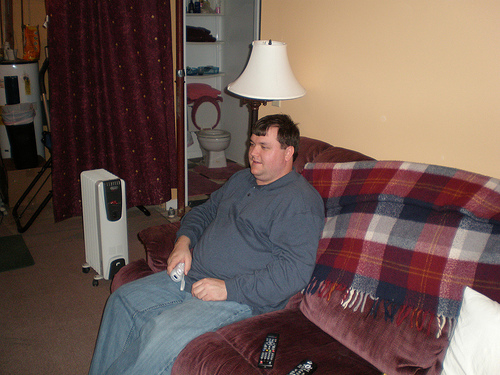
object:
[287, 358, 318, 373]
control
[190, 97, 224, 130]
cover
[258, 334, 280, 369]
controller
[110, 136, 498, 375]
couch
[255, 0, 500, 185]
wall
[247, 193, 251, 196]
button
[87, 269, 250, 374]
jeans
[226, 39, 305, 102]
lampshade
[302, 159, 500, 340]
blanket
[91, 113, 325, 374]
man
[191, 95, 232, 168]
toilet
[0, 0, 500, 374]
background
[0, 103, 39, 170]
can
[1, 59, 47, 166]
heater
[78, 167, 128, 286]
object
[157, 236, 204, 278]
hand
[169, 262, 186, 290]
wiimote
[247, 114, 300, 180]
head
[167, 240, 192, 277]
hand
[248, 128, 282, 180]
face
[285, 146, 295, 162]
ear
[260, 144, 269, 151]
eye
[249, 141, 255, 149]
eye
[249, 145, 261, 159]
nose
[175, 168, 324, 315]
shirt